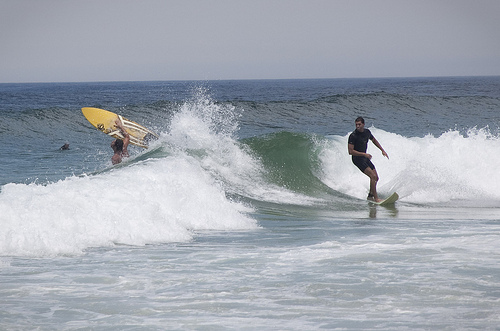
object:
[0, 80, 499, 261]
wave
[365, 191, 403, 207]
surfboard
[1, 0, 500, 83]
cloud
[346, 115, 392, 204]
man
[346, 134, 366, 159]
arm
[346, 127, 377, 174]
wet suit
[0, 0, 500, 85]
sky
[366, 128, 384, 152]
arm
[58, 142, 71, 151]
swimmer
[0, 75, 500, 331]
ocean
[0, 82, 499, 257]
foam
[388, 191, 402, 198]
tip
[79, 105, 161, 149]
surfboard